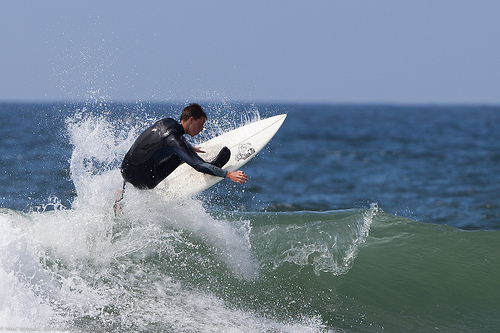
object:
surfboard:
[63, 113, 289, 240]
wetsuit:
[118, 117, 227, 189]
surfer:
[119, 103, 249, 191]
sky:
[1, 2, 500, 104]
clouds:
[6, 7, 500, 58]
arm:
[167, 135, 228, 178]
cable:
[113, 179, 126, 216]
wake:
[0, 191, 211, 332]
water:
[1, 103, 499, 333]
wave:
[0, 212, 499, 333]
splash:
[67, 115, 121, 275]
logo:
[235, 141, 256, 163]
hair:
[180, 103, 207, 122]